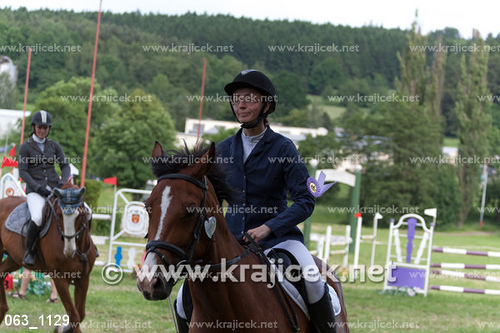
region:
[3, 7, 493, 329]
THE PICTURE IS COVERED IN WATERMARKS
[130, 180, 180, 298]
THE HORSE HAS WHITE MARKINGS ON HIS FACE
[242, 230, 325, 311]
THE RIDER IS WEARING WHITE PANTS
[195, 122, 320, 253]
THE RIDER'S JACKET IS GREY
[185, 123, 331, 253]
THE RIDER IS WEARING A JACKET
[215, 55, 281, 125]
THE RIDER'S HELMET IS BLACK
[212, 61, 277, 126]
THE RIDER IS WEARING A HELMET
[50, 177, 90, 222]
THE HORSE IS WEARING SOMETHING STRANGE ON HIS HEAD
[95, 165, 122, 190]
THIS FLAG IS RED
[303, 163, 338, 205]
THIS IS A BLUE RIBBON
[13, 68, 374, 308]
two women riding horses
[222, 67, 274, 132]
a woman wearing a riding helmet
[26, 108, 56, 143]
a woman wearing a riding helmet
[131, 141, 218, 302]
the head of a horse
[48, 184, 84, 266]
the head of a horse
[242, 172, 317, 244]
the arm of a woman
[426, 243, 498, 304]
an equestrian jumping fence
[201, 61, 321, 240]
a woman wearing a blue jacket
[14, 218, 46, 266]
black leather riding boots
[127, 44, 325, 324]
a woman riding a horse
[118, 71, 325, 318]
a woman riding a horse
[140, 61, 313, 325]
a woman riding a horse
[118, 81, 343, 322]
a woman riding a horse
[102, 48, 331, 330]
a woman riding a horse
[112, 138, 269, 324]
the horse is brown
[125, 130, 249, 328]
the horse is brown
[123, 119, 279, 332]
the horse is brown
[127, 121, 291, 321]
the horse is brown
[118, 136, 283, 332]
the horse is brown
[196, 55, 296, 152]
the head of a woman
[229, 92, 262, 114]
the nose of a woman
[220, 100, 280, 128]
the mouth of a woman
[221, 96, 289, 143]
the chin of a woman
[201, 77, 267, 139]
the face of a woman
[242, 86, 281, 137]
the ear of a woman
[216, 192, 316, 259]
the hand of a woman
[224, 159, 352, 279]
the arm of a woman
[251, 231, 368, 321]
the leg of a woman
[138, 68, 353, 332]
Woman riding a horse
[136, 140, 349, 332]
Mostly brown horse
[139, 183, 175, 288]
White on a horses face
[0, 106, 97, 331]
Woman steering a horse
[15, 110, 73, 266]
Woman wearing white horseriding pants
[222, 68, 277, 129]
Black jock helmet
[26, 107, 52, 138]
Black and white jock helmet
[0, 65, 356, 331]
Two women at a horseriding competition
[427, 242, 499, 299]
White and purple striped poles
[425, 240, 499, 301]
Horizontal horse jumping poles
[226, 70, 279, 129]
person has a head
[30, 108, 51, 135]
person has a head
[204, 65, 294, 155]
the head of a woman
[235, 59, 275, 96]
the helmet of a woman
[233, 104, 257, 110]
the nose of a woman